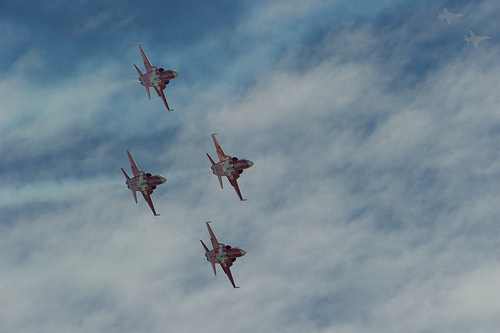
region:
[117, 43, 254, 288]
Four military jets flying in sequence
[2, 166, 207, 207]
A contrail left behind a flying jet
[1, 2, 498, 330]
Heavy cloud coverage during the day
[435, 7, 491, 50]
Two additional jets flying in the distance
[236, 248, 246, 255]
The nose of a jet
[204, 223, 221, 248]
The left wing of a jet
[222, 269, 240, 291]
The right wing of a jet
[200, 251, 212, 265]
The twin exhausts of a jet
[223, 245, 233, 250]
The left air intake of a jet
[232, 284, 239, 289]
A jet winglet on the wing's tip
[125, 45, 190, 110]
military jet plane in formation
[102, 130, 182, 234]
military jet plane in formation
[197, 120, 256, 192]
military jet plane in formation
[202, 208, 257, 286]
military jet plane in formation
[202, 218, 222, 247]
wing of military jet plane in formation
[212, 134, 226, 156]
wing of military jet plane in formation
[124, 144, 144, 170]
wing of military jet plane in formation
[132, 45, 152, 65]
wing of military jet plane in formation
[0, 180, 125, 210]
white contrail from jet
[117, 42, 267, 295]
jets in a blue sky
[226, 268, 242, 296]
a wing on a plane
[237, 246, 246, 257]
a nose on a plane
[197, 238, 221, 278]
tail wings of a plane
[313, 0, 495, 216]
white and blue clouds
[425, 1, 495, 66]
reflections of planes in a sky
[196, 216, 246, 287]
a red and white plane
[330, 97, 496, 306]
a white and blue sky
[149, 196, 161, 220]
the right wing of a plane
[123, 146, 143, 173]
left wing of a plane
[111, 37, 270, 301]
four jets are in the sky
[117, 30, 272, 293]
the jets are flying at an angle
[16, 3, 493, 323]
the sky is full of clouds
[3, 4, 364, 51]
a portion of the sky is blue in color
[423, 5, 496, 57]
two jets can be seen to the right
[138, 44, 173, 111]
the jets wings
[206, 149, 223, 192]
two smaller wings the jet has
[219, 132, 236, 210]
a part of the jet is grey in color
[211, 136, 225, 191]
a portion of the jet red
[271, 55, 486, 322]
several fluffy clouds are in the sky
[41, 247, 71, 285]
white cloud in sky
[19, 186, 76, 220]
white cloud in sky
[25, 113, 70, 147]
white cloud in sky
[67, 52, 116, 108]
white cloud in sky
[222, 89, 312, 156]
white cloud in sky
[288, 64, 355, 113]
white cloud in sky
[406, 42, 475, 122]
white cloud in sky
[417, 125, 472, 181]
white cloud in sky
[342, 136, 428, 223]
white cloud in sky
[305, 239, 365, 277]
white cloud in sky